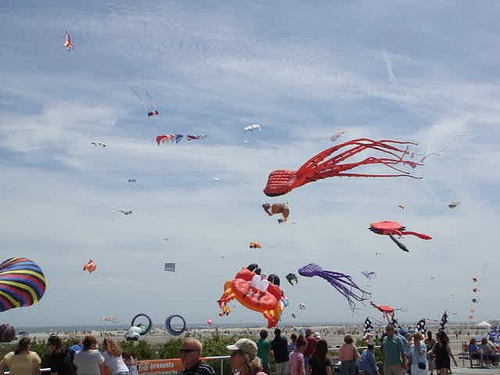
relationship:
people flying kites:
[0, 317, 498, 372] [2, 14, 474, 337]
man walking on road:
[375, 318, 408, 372] [367, 345, 479, 361]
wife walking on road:
[406, 325, 431, 371] [367, 345, 479, 361]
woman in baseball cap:
[218, 336, 267, 370] [226, 336, 259, 354]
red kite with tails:
[262, 137, 425, 197] [289, 129, 419, 189]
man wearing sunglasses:
[167, 331, 226, 373] [174, 347, 198, 353]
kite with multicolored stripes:
[0, 254, 46, 305] [0, 255, 45, 312]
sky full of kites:
[5, 2, 497, 321] [2, 14, 474, 337]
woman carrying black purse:
[404, 327, 427, 373] [413, 344, 428, 370]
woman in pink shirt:
[289, 330, 309, 373] [285, 350, 308, 374]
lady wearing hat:
[224, 335, 269, 373] [226, 335, 261, 354]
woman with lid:
[98, 333, 131, 374] [225, 336, 257, 355]